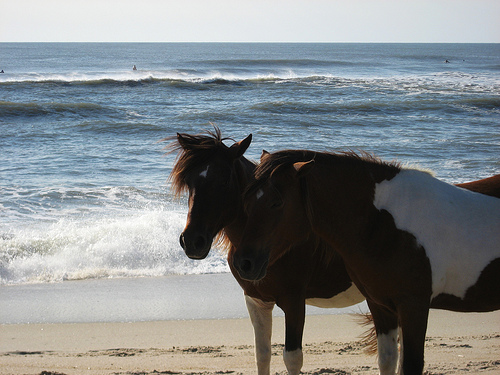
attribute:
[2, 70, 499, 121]
waves — white, blue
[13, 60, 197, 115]
waves — white, blue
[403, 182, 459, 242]
whit spot — white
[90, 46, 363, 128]
waves — white, blue, ocean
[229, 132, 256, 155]
ear — brown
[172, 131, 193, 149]
ear — brown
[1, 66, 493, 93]
waves — white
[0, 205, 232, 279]
waves — white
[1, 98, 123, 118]
waves — white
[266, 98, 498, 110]
waves — white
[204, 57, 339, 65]
waves — white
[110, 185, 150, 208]
ocean waves — blue, white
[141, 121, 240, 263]
horse — brown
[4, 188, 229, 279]
waves — white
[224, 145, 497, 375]
horse — brown, white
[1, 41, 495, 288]
waves — white, blue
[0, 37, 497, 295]
water — body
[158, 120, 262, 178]
mane — brown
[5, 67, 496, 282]
waves — white, blue, ocean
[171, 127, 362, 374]
horse — brown, white